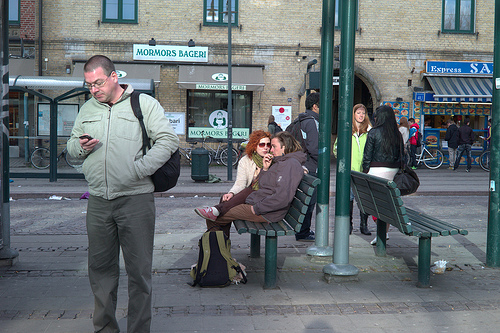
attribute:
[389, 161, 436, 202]
backpack — black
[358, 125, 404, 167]
jacket — black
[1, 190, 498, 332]
street — city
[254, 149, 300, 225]
sweatshirt — blue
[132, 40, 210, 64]
sign — green, white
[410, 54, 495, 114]
awning — blue, silver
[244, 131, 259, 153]
hair — red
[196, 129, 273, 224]
woman — curly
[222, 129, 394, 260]
bench — empty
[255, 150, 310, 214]
sweatshirt — hooded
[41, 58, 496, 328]
bus stop — green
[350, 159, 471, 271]
green bench — wooden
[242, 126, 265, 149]
hair — red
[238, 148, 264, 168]
scarf — green